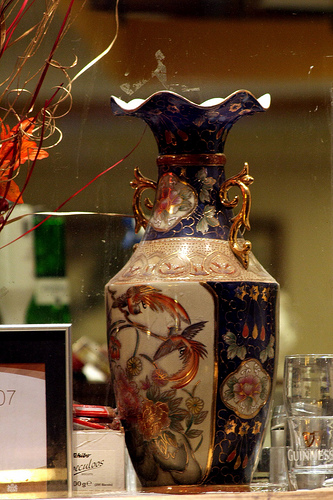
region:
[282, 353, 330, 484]
clear glass cup with liquor in it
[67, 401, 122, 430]
candybars on top of the box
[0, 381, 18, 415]
07 on the picture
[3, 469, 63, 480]
gold on the bottom of the picture frame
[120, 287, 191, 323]
orange decoration on the vase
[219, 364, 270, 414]
flower on the vase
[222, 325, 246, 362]
green leaf on the vase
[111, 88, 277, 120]
top of the vase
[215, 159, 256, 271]
gold decorative piece on the vase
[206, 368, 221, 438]
gold stripe on the vase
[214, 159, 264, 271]
has a gold handle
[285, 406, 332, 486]
Guinness beer glass next to vase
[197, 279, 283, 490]
vase has a dark blue panel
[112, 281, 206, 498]
vase has a cream colored panel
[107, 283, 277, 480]
vase has flowers on it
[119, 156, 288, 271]
vase has twp visible handles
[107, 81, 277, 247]
vase has a dark blue neck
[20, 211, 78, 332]
green bottle in background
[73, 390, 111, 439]
red wrappers next to vase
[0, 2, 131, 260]
floral next to vase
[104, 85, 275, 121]
the mouth of the vase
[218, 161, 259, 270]
a gold handle on the vase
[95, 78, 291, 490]
a large ornamented vase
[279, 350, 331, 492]
a clear glass on the table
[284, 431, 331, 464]
a label on the glass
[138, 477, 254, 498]
the base of the vase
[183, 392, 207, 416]
a flower on the vase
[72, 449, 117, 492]
writing on the box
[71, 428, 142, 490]
a white cardboard box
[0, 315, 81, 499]
a picture frame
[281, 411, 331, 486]
Guinness Shot Glass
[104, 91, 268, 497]
Antique Vase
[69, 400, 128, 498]
Box filled with strike matches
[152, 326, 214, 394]
red and orange bird flying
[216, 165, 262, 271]
Golden shiny handle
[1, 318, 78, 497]
Silver Outlined Picture Framed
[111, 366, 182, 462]
Variety of elegant painted flowers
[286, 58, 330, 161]
Dirty smeared mirror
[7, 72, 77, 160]
Gold And Red Decorative material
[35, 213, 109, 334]
reflection of the room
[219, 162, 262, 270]
Solid gold accents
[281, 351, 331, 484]
Guinness drinking glass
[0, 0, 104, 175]
Decorative flower pieces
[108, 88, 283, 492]
Beautiful elegant vase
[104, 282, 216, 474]
Flowers and birds designed with gold flowing through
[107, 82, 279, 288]
roses, and gold accents with dark blue background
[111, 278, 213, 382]
playful birds flying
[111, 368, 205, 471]
beautiful roses with gold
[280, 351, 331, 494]
drinking glasses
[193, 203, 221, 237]
green and gold leaves